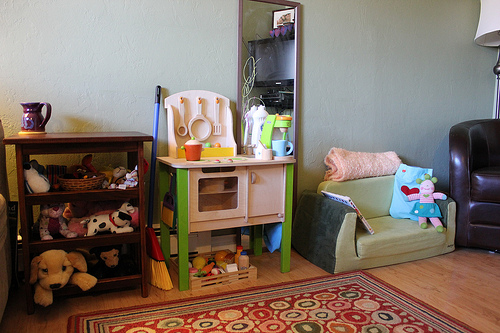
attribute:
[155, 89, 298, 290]
kitchen playset — small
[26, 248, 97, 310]
dog — stuffed, brown, large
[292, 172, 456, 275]
couch — green, child size, play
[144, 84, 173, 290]
broom — red blue, yellow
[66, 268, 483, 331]
rug — red green, white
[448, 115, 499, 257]
couch — leather, dark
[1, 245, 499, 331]
floor — wood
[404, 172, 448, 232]
doll — stuffed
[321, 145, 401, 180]
blanket — pink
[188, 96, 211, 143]
cooking pan — play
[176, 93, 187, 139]
spoon — play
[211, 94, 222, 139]
spatula — play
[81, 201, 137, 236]
stuffed animal — white, black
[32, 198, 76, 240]
stuffed animal — gray